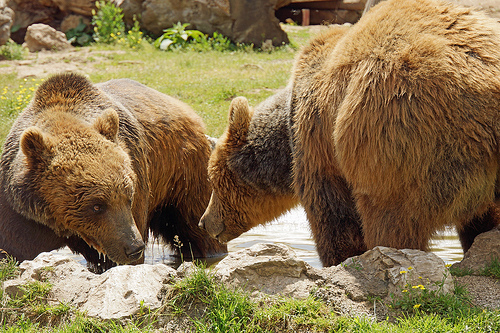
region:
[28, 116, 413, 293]
Two bears facing one another.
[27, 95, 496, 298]
The bears are standing in the water.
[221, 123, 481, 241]
The bear is near the big rock.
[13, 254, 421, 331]
Rocks in the grass.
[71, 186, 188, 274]
The bear has a big nose.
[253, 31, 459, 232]
The bear is brown and hairy.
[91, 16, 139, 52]
The plants have yellow flowers.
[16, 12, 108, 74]
A big rock near the flowers.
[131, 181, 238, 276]
The bear is wet at the bottom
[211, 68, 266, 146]
The bear ears are standing straight up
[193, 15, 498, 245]
The bear is brown.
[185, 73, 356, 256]
The bear is looking down.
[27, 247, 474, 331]
grey sharp rocks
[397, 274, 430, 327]
This flower is yellow.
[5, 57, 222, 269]
The bear is brown.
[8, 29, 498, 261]
Two bears by the rocks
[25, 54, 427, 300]
two bears looking at each other.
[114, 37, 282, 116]
The grass is sparse and dying.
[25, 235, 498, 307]
The rocks are grey.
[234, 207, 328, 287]
They are by water.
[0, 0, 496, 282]
Two bears are together.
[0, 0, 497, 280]
The bears are brown.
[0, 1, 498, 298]
The bears stand in water.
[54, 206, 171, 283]
Water drips from the bear's mouth.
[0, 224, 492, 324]
Rocks are next to the bears.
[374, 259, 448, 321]
Flowers grow next to the rocks.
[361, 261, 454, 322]
The flowers are yellow.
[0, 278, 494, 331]
Grass grows next to the rocks.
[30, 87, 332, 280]
The bears look at each other.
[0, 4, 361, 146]
Sunlight shines on the grass.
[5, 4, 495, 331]
2 Bears Carefully Drinking Water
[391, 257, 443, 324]
Dandelions Growing in the Wild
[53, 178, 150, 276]
Wet Whiskers from Drinking Water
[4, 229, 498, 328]
Rocks Near Stream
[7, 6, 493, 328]
2 Friends or Enemies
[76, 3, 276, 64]
Weeds Growing Wild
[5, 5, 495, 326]
Bears Drinking Water from Stream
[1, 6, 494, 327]
2 Brown and Black Bears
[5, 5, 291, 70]
Nice Sunny Day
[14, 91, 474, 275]
Refreshing Water for Drinking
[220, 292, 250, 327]
this is the grass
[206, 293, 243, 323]
the grass is green in color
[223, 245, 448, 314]
these are some rocks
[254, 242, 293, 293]
the rocks are grey in color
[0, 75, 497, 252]
these are some bears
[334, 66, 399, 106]
the bears are brown in color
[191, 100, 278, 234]
this is the bear's head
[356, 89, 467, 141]
the fur is rugged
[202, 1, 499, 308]
the bear is big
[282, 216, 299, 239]
this is the water